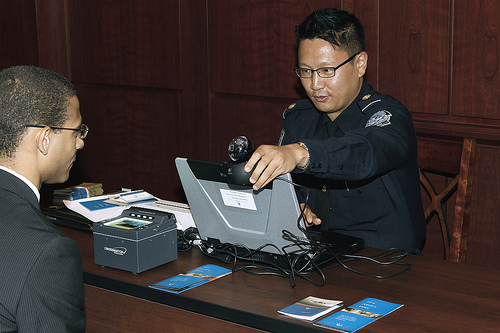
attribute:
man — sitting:
[1, 72, 87, 331]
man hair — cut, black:
[0, 66, 76, 156]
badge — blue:
[365, 111, 391, 128]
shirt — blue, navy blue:
[278, 86, 428, 249]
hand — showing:
[245, 142, 311, 189]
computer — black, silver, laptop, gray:
[168, 156, 365, 268]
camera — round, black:
[228, 135, 250, 160]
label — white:
[218, 188, 258, 213]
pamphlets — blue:
[277, 287, 404, 332]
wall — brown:
[1, 2, 499, 262]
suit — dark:
[1, 169, 84, 332]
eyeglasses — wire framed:
[295, 51, 363, 77]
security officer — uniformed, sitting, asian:
[242, 7, 427, 253]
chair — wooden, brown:
[413, 133, 475, 263]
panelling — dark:
[70, 0, 184, 200]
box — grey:
[93, 206, 179, 272]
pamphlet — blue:
[148, 254, 234, 293]